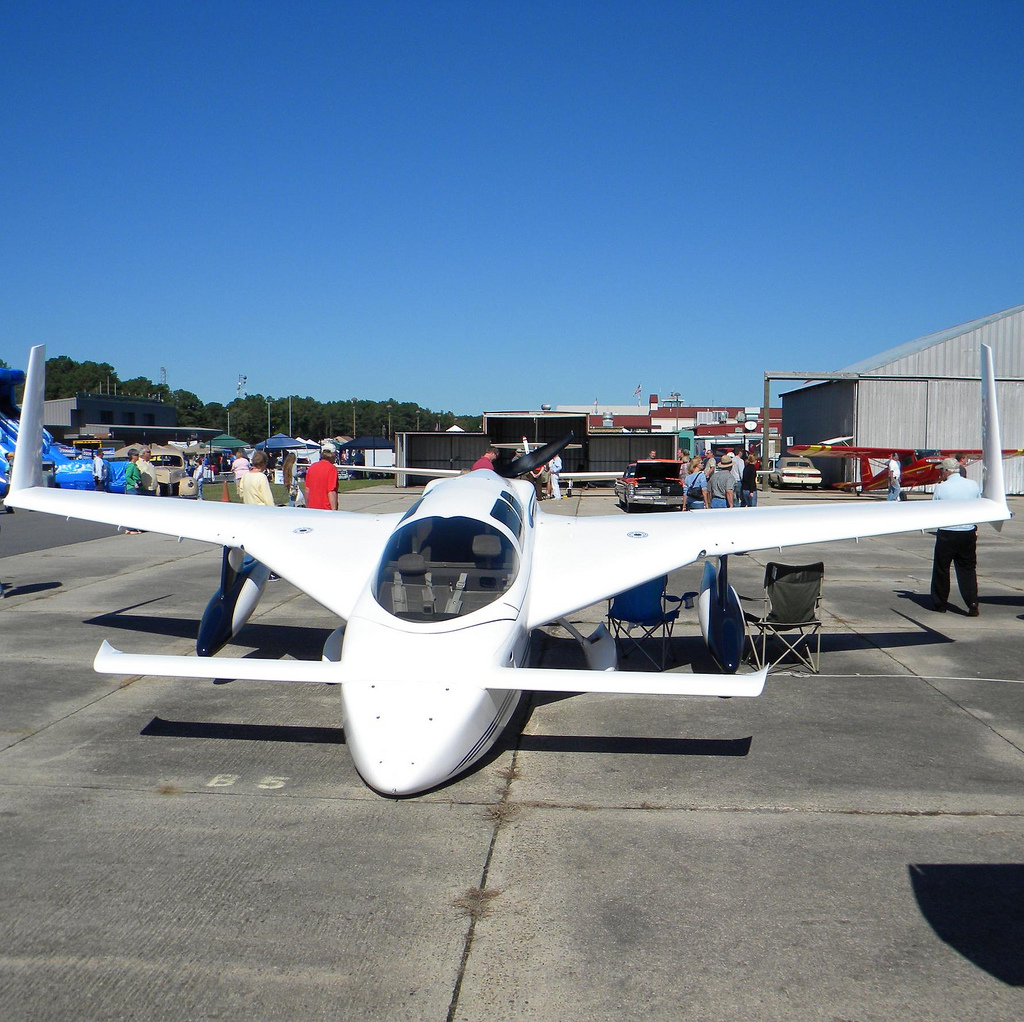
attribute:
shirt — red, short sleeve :
[303, 463, 330, 492]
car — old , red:
[625, 463, 686, 503]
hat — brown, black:
[921, 446, 974, 479]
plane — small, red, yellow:
[5, 338, 1008, 790]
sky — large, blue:
[3, 14, 1013, 358]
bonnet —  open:
[632, 462, 685, 499]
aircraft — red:
[782, 441, 1022, 493]